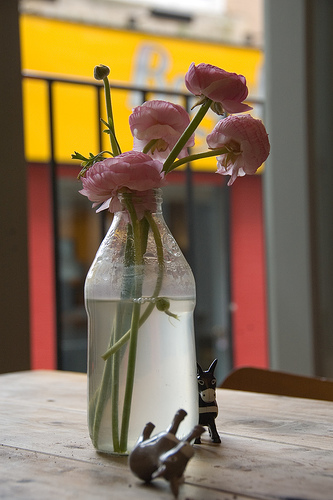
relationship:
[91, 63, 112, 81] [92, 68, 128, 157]
bud and stem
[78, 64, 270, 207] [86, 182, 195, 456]
flowers in vase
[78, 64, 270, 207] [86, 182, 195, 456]
flowers in bottle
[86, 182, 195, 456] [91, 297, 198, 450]
bottle full of water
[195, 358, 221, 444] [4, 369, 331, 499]
donkey on top of table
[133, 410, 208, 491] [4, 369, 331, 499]
donkey on top of table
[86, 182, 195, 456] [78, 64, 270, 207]
bottle of flowers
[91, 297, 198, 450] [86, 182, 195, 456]
water inside bottle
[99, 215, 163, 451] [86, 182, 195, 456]
stems inside bottle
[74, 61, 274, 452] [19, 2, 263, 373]
arragement near window